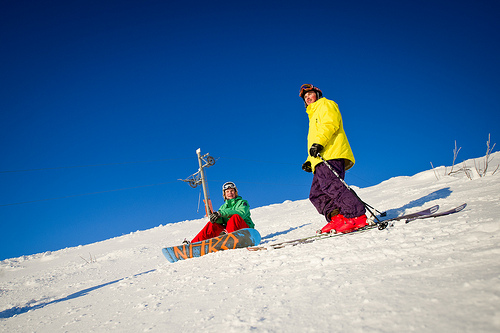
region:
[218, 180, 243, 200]
Boy wearing protective helmet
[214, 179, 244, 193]
Boy's goggles are raised on helmet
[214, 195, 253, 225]
Boy is wearing green ski jacket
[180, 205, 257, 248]
Boy is wearing red ski pants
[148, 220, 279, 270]
Boy fell from snowboard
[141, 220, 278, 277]
Boy's snowboard is blue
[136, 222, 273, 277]
Boy named his snowboard NIRO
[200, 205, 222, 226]
Boy is wearing warm gloves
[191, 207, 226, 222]
Boys gloves are black leather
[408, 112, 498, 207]
Weeds are sticking out of snow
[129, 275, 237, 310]
tiny snow drifts on the snow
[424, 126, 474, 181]
bare branches peeking out of the snow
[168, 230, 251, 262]
orange words on the snow board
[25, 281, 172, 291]
man's reflection on the snow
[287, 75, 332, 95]
red goggles on the man's hat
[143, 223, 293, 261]
blue snow board on the snow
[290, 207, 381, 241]
red shoes on the snow board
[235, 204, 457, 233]
large snow skis in the snow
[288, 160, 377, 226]
man wearing purple pants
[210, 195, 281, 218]
green and black jacket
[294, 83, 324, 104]
Man wearing protective helmet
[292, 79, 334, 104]
Man't helmet is black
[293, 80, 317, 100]
Man's goggles are on front of helmet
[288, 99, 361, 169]
Man wearing yellow jacket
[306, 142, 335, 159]
Man wearing black glove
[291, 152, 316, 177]
Man wearing black glove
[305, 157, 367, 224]
Man wearing ski pants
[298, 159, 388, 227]
Man's ski pants are purple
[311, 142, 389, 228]
Man using ski poles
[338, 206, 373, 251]
Man's ski boot is red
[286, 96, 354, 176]
guy's jacket is yellow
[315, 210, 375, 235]
guy wearing red shoes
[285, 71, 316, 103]
the goggles are orange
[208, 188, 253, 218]
woman's jacket is green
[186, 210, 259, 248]
woman's pants are red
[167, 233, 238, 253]
orange letters on snowboard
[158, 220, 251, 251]
the letters spell nitro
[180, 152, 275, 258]
girl sitting in snow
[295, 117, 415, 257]
man holding ski poles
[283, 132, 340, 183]
man's gloves are black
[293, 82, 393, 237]
male skier wearing yellow jacket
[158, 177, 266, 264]
female snowboarder in red pants and green jacket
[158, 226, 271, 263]
blue snowboard with orange lettering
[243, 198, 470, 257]
dark gray skis on a ski slope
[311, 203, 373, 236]
red ski boots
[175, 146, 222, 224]
ski lift support pole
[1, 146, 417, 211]
ski lift wires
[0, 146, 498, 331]
white snowy ski slope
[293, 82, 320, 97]
ski goggles with orange frame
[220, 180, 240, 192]
ski goggles